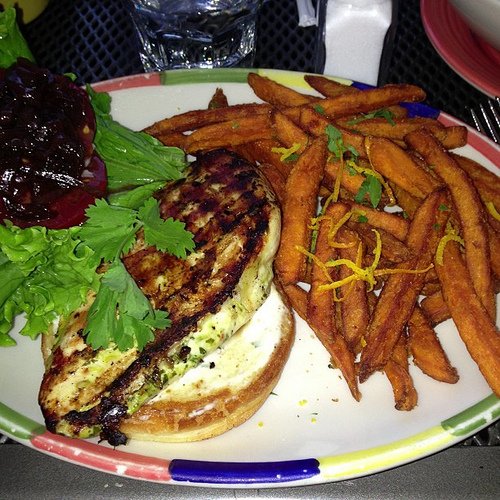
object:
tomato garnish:
[4, 58, 113, 226]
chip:
[357, 285, 422, 385]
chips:
[339, 225, 372, 348]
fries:
[346, 193, 426, 263]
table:
[0, 0, 500, 111]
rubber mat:
[11, 2, 500, 136]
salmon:
[291, 207, 434, 302]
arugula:
[0, 72, 196, 354]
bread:
[38, 147, 297, 447]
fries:
[247, 83, 494, 402]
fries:
[137, 72, 499, 412]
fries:
[312, 255, 500, 413]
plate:
[272, 408, 355, 454]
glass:
[132, 0, 261, 74]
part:
[345, 234, 358, 262]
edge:
[418, 0, 500, 100]